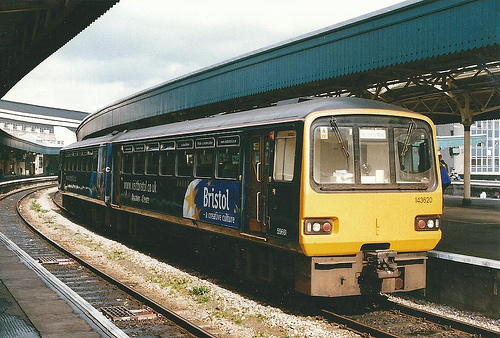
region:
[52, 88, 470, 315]
This is a train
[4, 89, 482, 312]
This is a yellow and blue train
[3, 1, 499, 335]
This is a railway station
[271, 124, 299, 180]
This is a train's window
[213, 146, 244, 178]
This is a train's window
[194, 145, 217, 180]
This is a train's window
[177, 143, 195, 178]
This is a train's window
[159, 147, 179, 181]
This is a train's window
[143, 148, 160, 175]
This is a train's window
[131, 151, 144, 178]
This is a train's window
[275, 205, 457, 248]
the headlights are on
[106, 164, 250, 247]
an advertisement on the side of the train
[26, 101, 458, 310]
the train is waiting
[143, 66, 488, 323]
the train is at the statin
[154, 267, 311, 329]
the rocks are white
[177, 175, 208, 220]
there are two gold stars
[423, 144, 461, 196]
people standing on the platform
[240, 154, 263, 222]
handles on the train door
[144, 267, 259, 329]
grass growing in the gravel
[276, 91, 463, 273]
the front of the train is yellow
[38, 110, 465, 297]
commuter train at the station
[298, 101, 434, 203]
windshield of train engine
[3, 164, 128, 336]
curve in train track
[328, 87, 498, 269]
station platform for train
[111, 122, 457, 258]
blue and yellow train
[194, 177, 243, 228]
"Bristol" on sign on train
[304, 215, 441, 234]
headlights on the train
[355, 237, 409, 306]
coupling on the train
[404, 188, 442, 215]
identification number on the train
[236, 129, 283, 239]
doors onto train car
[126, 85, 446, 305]
Lead car of a passenger train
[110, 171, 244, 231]
Advertisement on a passenger train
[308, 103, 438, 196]
Windshield on a passenger train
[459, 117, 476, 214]
Support for train station shelter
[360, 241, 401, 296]
Mechanism to hook trains together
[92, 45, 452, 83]
Roof of train station shelter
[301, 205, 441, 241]
Headlights on a passenger train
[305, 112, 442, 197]
Windshield on the passenger train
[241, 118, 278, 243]
Access door on a passenger train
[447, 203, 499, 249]
Train station platform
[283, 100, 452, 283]
Yellow train front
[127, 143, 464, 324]
Train on a commuter rail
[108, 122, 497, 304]
Train in a station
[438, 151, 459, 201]
Person waiting for a train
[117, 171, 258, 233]
Advertisement on a train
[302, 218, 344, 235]
Head light on train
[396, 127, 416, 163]
Wind shield wipers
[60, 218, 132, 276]
Patch of grass in train yard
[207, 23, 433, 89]
Green awing over train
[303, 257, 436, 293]
Metal rail on train